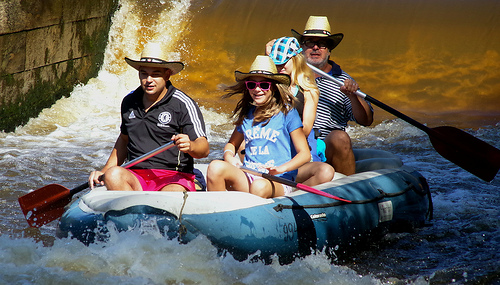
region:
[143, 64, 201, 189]
person on raft rowing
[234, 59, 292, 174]
person on raft rowing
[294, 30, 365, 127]
person on raft rowing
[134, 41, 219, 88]
cowboy hat on rafter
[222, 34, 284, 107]
cowboy hat on rafter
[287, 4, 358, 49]
cowboy hat on rafter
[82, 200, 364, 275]
white water below raft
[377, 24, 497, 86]
brown water behind raft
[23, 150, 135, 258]
red oar in person's hand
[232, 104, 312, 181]
blue t shirt on rafter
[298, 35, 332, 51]
man wearing black glasses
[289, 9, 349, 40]
man wearing tan hat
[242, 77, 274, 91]
girl wearing pink sunglasses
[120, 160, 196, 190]
man wearing red shorts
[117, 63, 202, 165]
man wearing black shirt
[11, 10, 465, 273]
four people white water rafting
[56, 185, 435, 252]
light blue raft boat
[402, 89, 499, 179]
long black water paddle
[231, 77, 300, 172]
girl wearing blue shirt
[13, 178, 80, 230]
large red water paddle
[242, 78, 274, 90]
Pink sunglasses on a girls face.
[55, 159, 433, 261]
Blue and white raft people are on.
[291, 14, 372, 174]
A man in the back with glasses on and a striped shirt.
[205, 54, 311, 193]
A girl smiling in pink glasses and a blue shirt.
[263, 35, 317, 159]
A barely visible blonde woman in a black top.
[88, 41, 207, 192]
A guy in a black and white striped shirt and pink shorts.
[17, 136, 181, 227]
A red paddle with pink and blue handle.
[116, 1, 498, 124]
A waterfall behind them.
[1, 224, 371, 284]
White water splashing in front of the raft.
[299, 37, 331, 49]
Black framed glasses on a man in the back.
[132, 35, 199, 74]
He is wearing a tan hat.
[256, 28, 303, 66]
She is wearing a helmet.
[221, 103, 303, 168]
She has a blue shirt on.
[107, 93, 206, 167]
He has a black shirt on.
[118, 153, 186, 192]
He has pink shorts on.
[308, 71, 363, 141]
He is wearing a striped shirt.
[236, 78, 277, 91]
She has sun glasses on.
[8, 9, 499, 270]
They are rafting.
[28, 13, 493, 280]
They are holding paddles.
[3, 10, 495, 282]
They are in the water.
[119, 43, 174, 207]
PERSON RIDING RAFT IN RAPIDS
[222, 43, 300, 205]
PERSON RIDING RAFT IN RAPIDS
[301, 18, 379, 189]
PERSON RIDING RAFT IN RAPIDS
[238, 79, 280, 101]
SUNGLASSES ON WOMAN'S FACE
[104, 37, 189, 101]
COWBOY HAT ON RAFTER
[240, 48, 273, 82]
COWBOY HAT ON RAFTER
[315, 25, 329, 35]
COWBOY HAT ON RAFTER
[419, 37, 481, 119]
BROWN WATER BEHIND RAFT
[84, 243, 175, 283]
WHITE WATER BENEATH RAFT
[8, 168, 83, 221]
RED OAR IN HAND